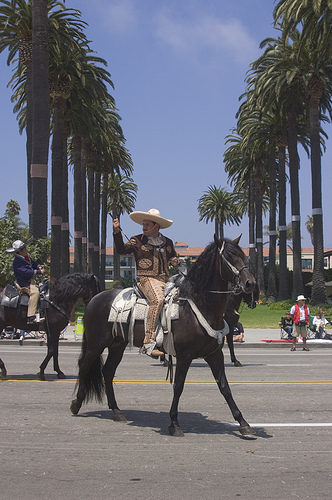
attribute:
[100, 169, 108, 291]
tree trunk — straight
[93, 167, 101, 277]
tree trunk — straight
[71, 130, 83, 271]
tree trunk — straight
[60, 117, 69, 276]
tree trunk — straight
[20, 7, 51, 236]
tree — straight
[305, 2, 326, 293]
trunk — straight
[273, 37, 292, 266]
tree — straight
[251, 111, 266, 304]
tree — straight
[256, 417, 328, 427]
line — white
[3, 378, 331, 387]
lines — yellow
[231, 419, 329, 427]
line — white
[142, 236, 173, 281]
top — brown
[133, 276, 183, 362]
pants — light brown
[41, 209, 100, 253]
trees — paint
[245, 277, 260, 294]
horse — snout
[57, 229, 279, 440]
horse — black mane 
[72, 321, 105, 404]
horse — black tail 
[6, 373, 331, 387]
line — yellow 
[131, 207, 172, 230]
hat — straw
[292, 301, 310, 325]
vest — red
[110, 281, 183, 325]
blanket — white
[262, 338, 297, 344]
towel — red